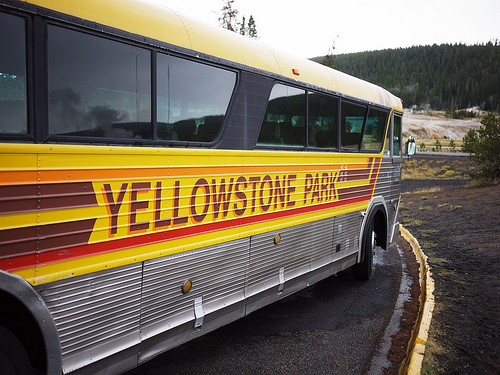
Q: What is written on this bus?
A: Yellowstone Park.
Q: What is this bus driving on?
A: Street.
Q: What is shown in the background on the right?
A: Trees.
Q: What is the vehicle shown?
A: Bus.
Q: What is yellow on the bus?
A: Roof and logo.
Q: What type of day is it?
A: Cloudy.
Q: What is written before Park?
A: Yellowstone.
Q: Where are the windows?
A: On the bus.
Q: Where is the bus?
A: On the road.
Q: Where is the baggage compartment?
A: On the side of the bus.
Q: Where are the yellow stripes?
A: On the side of the bus.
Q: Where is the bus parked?
A: On the road.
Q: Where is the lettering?
A: On the side of the bus.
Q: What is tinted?
A: The bus windows.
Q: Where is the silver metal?
A: On the side of the bus.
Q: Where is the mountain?
A: In the distance.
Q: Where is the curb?
A: Beside the bus.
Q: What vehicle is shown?
A: Bus.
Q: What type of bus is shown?
A: Tour.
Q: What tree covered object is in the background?
A: Mountain.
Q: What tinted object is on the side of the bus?
A: Windows.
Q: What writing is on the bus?
A: YELLOWSTONE PARK.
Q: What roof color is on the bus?
A: Yellow.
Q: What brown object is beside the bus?
A: Dirt.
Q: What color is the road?
A: Grey.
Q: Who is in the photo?
A: Nobody.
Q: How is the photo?
A: Clear.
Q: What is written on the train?
A: Yellowstone park.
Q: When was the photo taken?
A: During the day.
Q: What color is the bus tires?
A: Black.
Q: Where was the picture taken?
A: On a winding road.